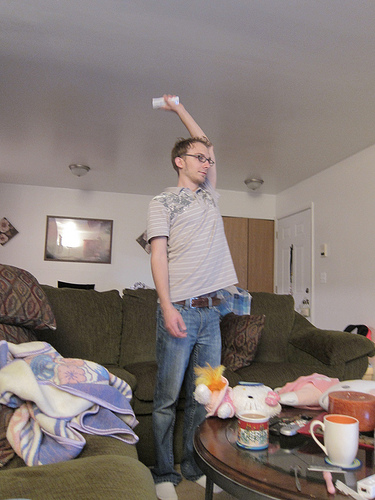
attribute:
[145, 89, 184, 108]
gamecontoller — white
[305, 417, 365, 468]
mug — white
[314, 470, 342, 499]
candle — orange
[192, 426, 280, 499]
table — brown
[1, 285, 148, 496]
couch — green, pink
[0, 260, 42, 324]
pillow — brown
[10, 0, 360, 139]
ceiling — white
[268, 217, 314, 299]
door — white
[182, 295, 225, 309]
belt — brown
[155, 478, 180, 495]
socks — white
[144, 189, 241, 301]
shirt — gray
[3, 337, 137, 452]
blanket — pink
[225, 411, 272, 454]
coffee — green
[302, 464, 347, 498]
dogbrush — pink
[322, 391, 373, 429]
candle — brown, orange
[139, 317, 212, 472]
jeans — blue